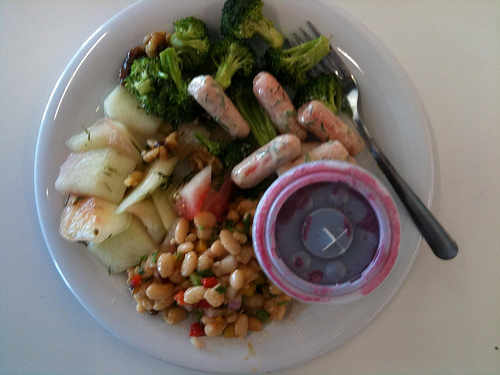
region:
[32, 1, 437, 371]
plate with a healthy meal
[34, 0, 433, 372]
circular, white, shiny plate with food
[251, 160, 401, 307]
container with sauce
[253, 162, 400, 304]
small container with a red sauce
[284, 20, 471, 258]
silver fork on the side of plate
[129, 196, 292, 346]
small tan beans on the side next to sauce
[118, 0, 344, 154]
green broccoli on plate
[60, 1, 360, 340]
healthy looking meal on plate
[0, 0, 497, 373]
white surface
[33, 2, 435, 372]
white plate on a white surface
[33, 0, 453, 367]
a white dish with food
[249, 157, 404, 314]
a small cup with red souce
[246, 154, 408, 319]
cup has a lid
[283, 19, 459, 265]
a fork on side a dish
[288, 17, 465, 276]
fork is color silver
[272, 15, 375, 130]
part of fork under vegetables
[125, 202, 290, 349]
small beans on a dish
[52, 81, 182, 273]
a side of potatoes on a dish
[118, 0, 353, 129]
pieces of broccoli on side a dish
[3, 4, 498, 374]
dish is on a white surface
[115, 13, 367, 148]
Steamed green garlicy brocolli florets.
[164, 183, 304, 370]
Multiple bean and sauce salad.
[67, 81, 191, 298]
Cucumber and fennel cold salad.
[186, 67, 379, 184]
Mini spicy chicken sausage unsmoked.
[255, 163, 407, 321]
Small container of Red Plum Sauce.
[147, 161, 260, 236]
Fresh ripe red strawberries on top of the bean salad.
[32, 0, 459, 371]
A white plate with lights reflecting on it.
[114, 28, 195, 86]
Crumbled candy coated shelled.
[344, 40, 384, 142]
A light reflects itself on the fork.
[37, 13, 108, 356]
There are lights reflecting on the side of the plate.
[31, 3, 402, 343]
Vegetarian meal with dipping sauce.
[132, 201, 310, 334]
Navy bean caviar with red peppers.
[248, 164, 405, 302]
Plastic container of dipping sauce.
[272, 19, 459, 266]
Stainless steel fork for utensil.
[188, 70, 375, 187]
Tofu sausages with spices.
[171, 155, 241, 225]
Fresh garden ripe tomato pieces.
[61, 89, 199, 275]
Cucumber salad with dill.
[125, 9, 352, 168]
Fresh green broccoli with walnuts.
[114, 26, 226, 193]
Brown walnut pieces for flavor.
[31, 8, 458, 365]
White dinner plate of food.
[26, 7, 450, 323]
a plate of food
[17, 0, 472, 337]
the plate is white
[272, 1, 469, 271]
the fork is on the plate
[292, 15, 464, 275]
the fork is silver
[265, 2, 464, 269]
the fork is shiny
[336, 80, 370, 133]
light is reflecting in the fork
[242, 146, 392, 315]
a container of red sauce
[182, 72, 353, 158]
carrots in white sauce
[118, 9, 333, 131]
pieces of broccoli florets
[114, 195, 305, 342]
white beans on the plate